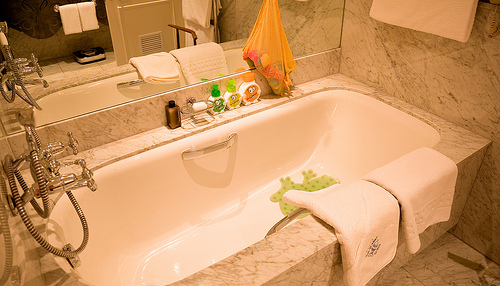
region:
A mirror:
[0, 0, 347, 135]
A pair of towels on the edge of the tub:
[280, 145, 458, 285]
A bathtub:
[3, 72, 493, 284]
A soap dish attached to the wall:
[179, 95, 216, 114]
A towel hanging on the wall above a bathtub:
[368, 0, 480, 44]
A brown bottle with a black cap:
[164, 99, 183, 129]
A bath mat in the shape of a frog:
[270, 159, 340, 218]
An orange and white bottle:
[240, 71, 260, 104]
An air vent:
[139, 31, 164, 54]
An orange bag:
[243, 0, 296, 97]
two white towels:
[277, 152, 496, 281]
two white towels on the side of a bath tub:
[58, 57, 470, 259]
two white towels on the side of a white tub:
[60, 74, 497, 264]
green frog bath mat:
[238, 152, 390, 259]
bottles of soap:
[129, 60, 359, 157]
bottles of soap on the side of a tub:
[43, 67, 488, 280]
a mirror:
[5, 2, 353, 74]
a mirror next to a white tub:
[27, 0, 342, 104]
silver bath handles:
[14, 117, 146, 242]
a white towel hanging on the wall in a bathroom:
[349, 0, 487, 42]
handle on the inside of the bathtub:
[177, 127, 254, 169]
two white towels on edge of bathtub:
[275, 144, 471, 275]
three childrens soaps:
[206, 77, 263, 109]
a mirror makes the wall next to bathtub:
[2, 0, 361, 115]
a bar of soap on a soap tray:
[180, 92, 215, 122]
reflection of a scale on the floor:
[70, 40, 110, 65]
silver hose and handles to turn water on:
[7, 119, 104, 266]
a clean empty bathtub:
[21, 84, 468, 276]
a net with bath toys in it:
[245, 2, 303, 94]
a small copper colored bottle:
[162, 92, 192, 132]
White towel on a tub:
[277, 202, 409, 239]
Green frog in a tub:
[256, 161, 343, 221]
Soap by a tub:
[166, 85, 305, 137]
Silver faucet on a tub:
[6, 143, 136, 232]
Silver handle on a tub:
[174, 127, 271, 155]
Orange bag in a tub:
[247, 3, 321, 93]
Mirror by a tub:
[33, 26, 255, 116]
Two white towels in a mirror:
[141, 39, 258, 117]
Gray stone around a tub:
[62, 97, 245, 282]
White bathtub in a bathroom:
[22, 126, 437, 258]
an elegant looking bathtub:
[12, 73, 493, 283]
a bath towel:
[289, 175, 406, 280]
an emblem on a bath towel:
[366, 230, 383, 261]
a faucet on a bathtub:
[11, 118, 103, 202]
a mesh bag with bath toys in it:
[239, 2, 299, 97]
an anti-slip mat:
[269, 165, 336, 190]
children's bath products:
[206, 74, 264, 112]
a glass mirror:
[12, 8, 235, 83]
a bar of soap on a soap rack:
[185, 97, 215, 114]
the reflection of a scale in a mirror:
[72, 47, 112, 64]